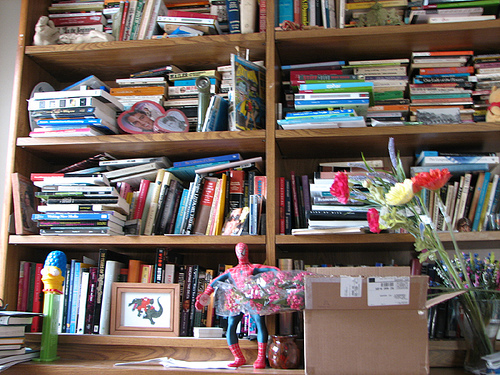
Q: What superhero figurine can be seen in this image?
A: Spider Man.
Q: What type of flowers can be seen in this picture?
A: Carnations.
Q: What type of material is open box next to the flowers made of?
A: Cardboard.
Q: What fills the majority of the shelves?
A: Books.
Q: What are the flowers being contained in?
A: A vase.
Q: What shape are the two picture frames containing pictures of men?
A: Heart.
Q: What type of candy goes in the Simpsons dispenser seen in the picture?
A: Pez.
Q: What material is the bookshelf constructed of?
A: Wood.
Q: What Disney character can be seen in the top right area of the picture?
A: Winnie The Pooh.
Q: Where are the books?
A: On shelf.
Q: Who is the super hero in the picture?
A: Spider Man.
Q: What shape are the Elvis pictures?
A: Hearts.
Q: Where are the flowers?
A: In vase.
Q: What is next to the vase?
A: A box.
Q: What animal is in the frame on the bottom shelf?
A: Alligator.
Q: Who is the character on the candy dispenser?
A: Marge Simpson.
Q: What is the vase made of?
A: Glass.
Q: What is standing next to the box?
A: Spiderman.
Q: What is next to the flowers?
A: A brown box.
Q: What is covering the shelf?
A: Books.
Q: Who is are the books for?
A: People.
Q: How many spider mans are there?
A: One.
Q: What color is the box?
A: Brown.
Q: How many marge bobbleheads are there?
A: One.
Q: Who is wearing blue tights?
A: Spiderman.